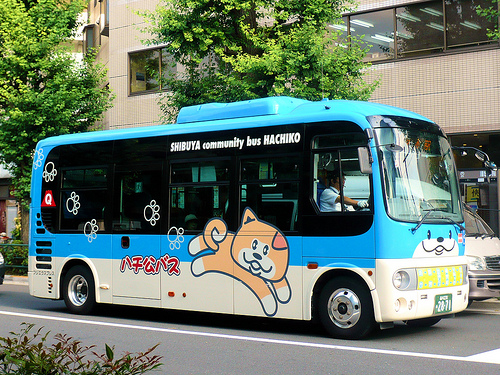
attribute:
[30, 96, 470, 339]
bus — blue, white, driving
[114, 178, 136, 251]
small puddles — water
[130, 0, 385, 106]
plant — green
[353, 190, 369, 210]
gloves — white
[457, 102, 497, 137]
ground — white